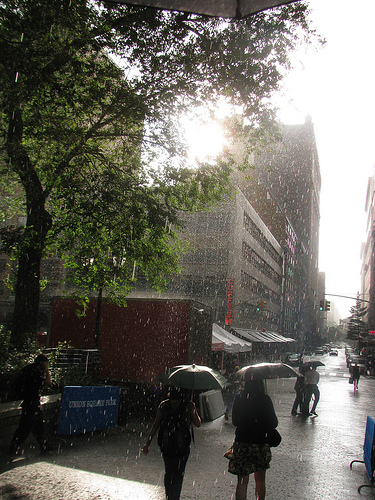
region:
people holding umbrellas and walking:
[133, 361, 307, 487]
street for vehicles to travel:
[323, 347, 342, 368]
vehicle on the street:
[327, 346, 339, 356]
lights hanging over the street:
[312, 297, 334, 313]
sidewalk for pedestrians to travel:
[258, 380, 350, 494]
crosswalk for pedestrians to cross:
[304, 361, 347, 380]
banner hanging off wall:
[55, 385, 124, 432]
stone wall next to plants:
[0, 399, 64, 441]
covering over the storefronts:
[246, 329, 293, 350]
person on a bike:
[344, 352, 371, 394]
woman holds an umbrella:
[225, 353, 303, 498]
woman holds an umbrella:
[136, 353, 231, 498]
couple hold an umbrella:
[287, 351, 329, 426]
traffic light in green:
[315, 289, 327, 314]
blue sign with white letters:
[50, 379, 125, 442]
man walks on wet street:
[338, 357, 358, 397]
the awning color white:
[206, 319, 252, 353]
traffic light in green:
[252, 296, 265, 319]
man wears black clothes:
[6, 343, 56, 461]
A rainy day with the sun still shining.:
[5, 9, 373, 494]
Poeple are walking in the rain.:
[0, 346, 361, 499]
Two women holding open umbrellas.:
[133, 349, 303, 499]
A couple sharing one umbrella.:
[282, 352, 329, 423]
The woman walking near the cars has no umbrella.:
[346, 359, 362, 397]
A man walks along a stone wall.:
[5, 351, 78, 461]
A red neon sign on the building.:
[222, 271, 236, 333]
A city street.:
[238, 208, 374, 446]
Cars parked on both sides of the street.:
[287, 326, 371, 373]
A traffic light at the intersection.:
[303, 287, 374, 357]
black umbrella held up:
[234, 357, 300, 379]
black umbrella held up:
[165, 353, 227, 392]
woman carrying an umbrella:
[202, 347, 307, 499]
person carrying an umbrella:
[153, 353, 223, 487]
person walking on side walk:
[0, 345, 61, 442]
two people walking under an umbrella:
[292, 349, 328, 422]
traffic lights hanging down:
[312, 300, 331, 316]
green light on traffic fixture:
[317, 300, 322, 312]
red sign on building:
[226, 276, 232, 314]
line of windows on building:
[237, 245, 285, 281]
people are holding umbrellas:
[157, 311, 301, 496]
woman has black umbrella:
[227, 345, 300, 406]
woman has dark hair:
[243, 369, 254, 395]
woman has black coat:
[232, 396, 273, 470]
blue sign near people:
[53, 361, 128, 436]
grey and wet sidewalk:
[284, 404, 340, 492]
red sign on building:
[218, 251, 244, 342]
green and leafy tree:
[2, 26, 229, 241]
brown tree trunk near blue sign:
[3, 86, 37, 363]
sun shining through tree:
[176, 108, 231, 176]